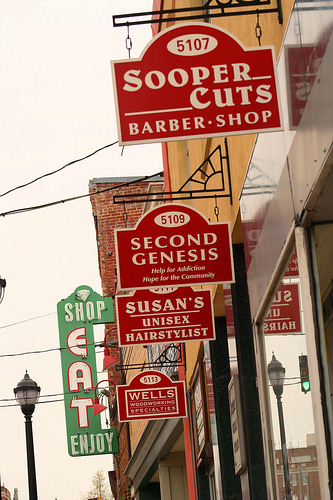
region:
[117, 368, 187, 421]
a red and white sign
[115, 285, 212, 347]
a red and white sign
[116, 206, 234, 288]
a red and white sign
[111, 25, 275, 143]
a red and white sign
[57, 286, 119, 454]
a green sign says eat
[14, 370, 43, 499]
lamp post is black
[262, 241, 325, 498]
a reflection on window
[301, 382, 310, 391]
the light is green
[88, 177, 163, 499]
the building made of brick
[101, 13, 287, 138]
a red and white business sign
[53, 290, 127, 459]
a green, white and red business sign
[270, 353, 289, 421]
a street lamp on a post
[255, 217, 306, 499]
a window on a building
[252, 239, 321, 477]
reflection in a window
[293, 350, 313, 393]
a street traffic light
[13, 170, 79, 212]
suspended utility cables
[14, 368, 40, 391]
the top of a street lamp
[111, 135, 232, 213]
a bracket holding a sign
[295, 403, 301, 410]
part of a window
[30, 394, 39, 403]
part of a light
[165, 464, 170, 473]
part of a door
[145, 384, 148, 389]
part of a post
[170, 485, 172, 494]
edge of a door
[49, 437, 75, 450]
part of the cloud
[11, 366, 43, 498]
A tall black street lamp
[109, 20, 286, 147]
A red and white sign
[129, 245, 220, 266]
The word "GENESIS" on a sign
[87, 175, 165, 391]
Brown bricks on a building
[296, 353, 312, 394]
A traffic light lit up green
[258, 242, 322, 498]
Reflections on the window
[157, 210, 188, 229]
The number "5109" on a sign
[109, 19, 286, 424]
Four red and white signs in a row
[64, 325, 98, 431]
The word "EAT" on a green sign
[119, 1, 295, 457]
The yellow side of a building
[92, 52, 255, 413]
four white and red signs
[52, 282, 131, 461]
a green and white sign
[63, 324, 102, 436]
white letters outlined in red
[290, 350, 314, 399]
a green traffic light in window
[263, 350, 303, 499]
reflection of street lamp in window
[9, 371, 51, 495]
a black and white street lamp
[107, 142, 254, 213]
a black metal hanger for sign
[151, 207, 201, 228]
red numbers on a sign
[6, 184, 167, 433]
wires in the air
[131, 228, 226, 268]
white letters on red sign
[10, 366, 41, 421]
light on the top of the pole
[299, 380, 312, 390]
green light on the signal light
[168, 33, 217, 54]
numbers on the sign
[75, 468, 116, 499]
tree in the distance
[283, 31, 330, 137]
reflection of the sign on the building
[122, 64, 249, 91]
white text on a sign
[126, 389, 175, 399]
white text on a sign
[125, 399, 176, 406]
white text on a sign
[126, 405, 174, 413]
white text on a sign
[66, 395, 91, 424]
white text on a sign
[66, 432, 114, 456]
white text on a sign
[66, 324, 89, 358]
white text on a sign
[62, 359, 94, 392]
white text on a sign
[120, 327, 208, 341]
white text on a sign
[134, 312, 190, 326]
white text on a sign